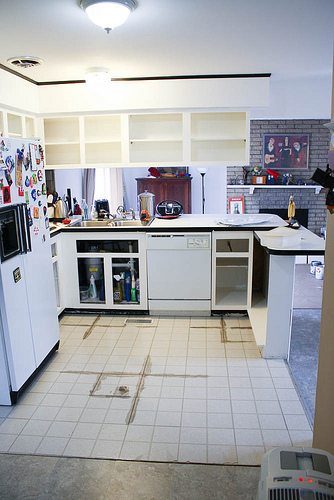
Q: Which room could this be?
A: It is a kitchen.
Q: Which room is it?
A: It is a kitchen.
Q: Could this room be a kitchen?
A: Yes, it is a kitchen.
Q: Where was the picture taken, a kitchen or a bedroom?
A: It was taken at a kitchen.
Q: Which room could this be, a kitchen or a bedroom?
A: It is a kitchen.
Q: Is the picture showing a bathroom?
A: No, the picture is showing a kitchen.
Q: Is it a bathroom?
A: No, it is a kitchen.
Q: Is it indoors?
A: Yes, it is indoors.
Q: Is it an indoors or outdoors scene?
A: It is indoors.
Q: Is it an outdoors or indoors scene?
A: It is indoors.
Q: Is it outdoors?
A: No, it is indoors.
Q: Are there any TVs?
A: No, there are no tvs.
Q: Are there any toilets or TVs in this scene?
A: No, there are no TVs or toilets.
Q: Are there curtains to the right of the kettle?
A: Yes, there is a curtain to the right of the kettle.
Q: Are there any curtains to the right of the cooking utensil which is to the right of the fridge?
A: Yes, there is a curtain to the right of the kettle.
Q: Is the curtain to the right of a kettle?
A: Yes, the curtain is to the right of a kettle.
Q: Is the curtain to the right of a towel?
A: No, the curtain is to the right of a kettle.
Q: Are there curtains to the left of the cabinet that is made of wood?
A: Yes, there is a curtain to the left of the cabinet.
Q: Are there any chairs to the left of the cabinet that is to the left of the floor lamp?
A: No, there is a curtain to the left of the cabinet.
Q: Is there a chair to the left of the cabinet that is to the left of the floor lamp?
A: No, there is a curtain to the left of the cabinet.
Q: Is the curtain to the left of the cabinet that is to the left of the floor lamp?
A: Yes, the curtain is to the left of the cabinet.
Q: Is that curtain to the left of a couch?
A: No, the curtain is to the left of the cabinet.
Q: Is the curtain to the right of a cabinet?
A: No, the curtain is to the left of a cabinet.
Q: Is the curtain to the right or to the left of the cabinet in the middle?
A: The curtain is to the left of the cabinet.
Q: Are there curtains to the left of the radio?
A: Yes, there is a curtain to the left of the radio.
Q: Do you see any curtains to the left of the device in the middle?
A: Yes, there is a curtain to the left of the radio.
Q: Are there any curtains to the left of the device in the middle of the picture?
A: Yes, there is a curtain to the left of the radio.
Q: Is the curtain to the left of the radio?
A: Yes, the curtain is to the left of the radio.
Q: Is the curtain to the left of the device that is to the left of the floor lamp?
A: Yes, the curtain is to the left of the radio.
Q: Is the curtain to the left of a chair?
A: No, the curtain is to the left of the radio.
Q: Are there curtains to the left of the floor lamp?
A: Yes, there is a curtain to the left of the floor lamp.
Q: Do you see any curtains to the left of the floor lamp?
A: Yes, there is a curtain to the left of the floor lamp.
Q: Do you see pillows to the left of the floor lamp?
A: No, there is a curtain to the left of the floor lamp.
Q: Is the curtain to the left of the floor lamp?
A: Yes, the curtain is to the left of the floor lamp.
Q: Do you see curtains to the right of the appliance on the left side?
A: Yes, there is a curtain to the right of the fridge.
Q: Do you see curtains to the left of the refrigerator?
A: No, the curtain is to the right of the refrigerator.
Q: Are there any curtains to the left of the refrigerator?
A: No, the curtain is to the right of the refrigerator.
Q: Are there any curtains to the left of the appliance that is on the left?
A: No, the curtain is to the right of the refrigerator.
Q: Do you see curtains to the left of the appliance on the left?
A: No, the curtain is to the right of the refrigerator.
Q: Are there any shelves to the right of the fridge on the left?
A: No, there is a curtain to the right of the freezer.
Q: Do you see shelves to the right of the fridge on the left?
A: No, there is a curtain to the right of the freezer.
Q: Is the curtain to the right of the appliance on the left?
A: Yes, the curtain is to the right of the refrigerator.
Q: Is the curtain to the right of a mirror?
A: No, the curtain is to the right of the refrigerator.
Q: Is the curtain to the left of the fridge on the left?
A: No, the curtain is to the right of the fridge.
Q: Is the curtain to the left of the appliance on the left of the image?
A: No, the curtain is to the right of the fridge.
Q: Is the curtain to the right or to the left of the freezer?
A: The curtain is to the right of the freezer.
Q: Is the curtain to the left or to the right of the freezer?
A: The curtain is to the right of the freezer.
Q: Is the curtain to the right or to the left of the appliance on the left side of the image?
A: The curtain is to the right of the freezer.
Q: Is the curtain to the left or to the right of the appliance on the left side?
A: The curtain is to the right of the freezer.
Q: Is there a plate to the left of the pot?
A: No, there is a curtain to the left of the pot.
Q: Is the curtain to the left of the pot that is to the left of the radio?
A: Yes, the curtain is to the left of the pot.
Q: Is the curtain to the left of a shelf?
A: No, the curtain is to the left of the pot.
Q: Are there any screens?
A: No, there are no screens.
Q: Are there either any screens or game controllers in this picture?
A: No, there are no screens or game controllers.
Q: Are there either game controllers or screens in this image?
A: No, there are no screens or game controllers.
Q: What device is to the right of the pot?
A: The device is a radio.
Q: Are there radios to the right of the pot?
A: Yes, there is a radio to the right of the pot.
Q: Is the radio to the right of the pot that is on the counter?
A: Yes, the radio is to the right of the pot.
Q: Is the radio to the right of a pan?
A: No, the radio is to the right of the pot.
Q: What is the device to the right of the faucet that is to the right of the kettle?
A: The device is a radio.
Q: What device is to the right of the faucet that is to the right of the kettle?
A: The device is a radio.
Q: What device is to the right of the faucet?
A: The device is a radio.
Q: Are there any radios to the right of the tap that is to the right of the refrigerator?
A: Yes, there is a radio to the right of the tap.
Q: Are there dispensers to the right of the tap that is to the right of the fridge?
A: No, there is a radio to the right of the faucet.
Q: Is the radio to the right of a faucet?
A: Yes, the radio is to the right of a faucet.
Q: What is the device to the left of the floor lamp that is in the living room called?
A: The device is a radio.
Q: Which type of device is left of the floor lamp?
A: The device is a radio.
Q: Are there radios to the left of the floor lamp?
A: Yes, there is a radio to the left of the floor lamp.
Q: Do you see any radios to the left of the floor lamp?
A: Yes, there is a radio to the left of the floor lamp.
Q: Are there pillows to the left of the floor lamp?
A: No, there is a radio to the left of the floor lamp.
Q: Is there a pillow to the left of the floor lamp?
A: No, there is a radio to the left of the floor lamp.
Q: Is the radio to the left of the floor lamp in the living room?
A: Yes, the radio is to the left of the floor lamp.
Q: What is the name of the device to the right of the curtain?
A: The device is a radio.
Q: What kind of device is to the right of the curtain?
A: The device is a radio.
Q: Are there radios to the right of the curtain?
A: Yes, there is a radio to the right of the curtain.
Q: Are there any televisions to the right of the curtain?
A: No, there is a radio to the right of the curtain.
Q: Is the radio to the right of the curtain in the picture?
A: Yes, the radio is to the right of the curtain.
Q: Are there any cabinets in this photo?
A: Yes, there is a cabinet.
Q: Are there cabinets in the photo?
A: Yes, there is a cabinet.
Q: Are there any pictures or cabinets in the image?
A: Yes, there is a cabinet.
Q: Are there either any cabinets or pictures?
A: Yes, there is a cabinet.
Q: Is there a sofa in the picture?
A: No, there are no sofas.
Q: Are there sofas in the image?
A: No, there are no sofas.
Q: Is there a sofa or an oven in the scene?
A: No, there are no sofas or ovens.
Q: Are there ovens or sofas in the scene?
A: No, there are no sofas or ovens.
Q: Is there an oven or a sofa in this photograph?
A: No, there are no sofas or ovens.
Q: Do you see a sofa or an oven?
A: No, there are no sofas or ovens.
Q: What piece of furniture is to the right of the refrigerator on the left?
A: The piece of furniture is a cabinet.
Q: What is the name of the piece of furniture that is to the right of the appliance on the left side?
A: The piece of furniture is a cabinet.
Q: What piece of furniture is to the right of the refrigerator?
A: The piece of furniture is a cabinet.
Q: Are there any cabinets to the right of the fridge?
A: Yes, there is a cabinet to the right of the fridge.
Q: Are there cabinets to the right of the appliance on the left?
A: Yes, there is a cabinet to the right of the fridge.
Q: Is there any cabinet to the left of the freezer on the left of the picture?
A: No, the cabinet is to the right of the freezer.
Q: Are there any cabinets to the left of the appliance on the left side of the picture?
A: No, the cabinet is to the right of the freezer.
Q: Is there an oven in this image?
A: No, there are no ovens.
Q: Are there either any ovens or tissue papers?
A: No, there are no ovens or tissue papers.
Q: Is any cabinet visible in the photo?
A: Yes, there is a cabinet.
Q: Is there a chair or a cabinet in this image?
A: Yes, there is a cabinet.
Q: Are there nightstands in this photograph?
A: No, there are no nightstands.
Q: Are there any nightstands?
A: No, there are no nightstands.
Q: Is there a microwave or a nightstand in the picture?
A: No, there are no nightstands or microwaves.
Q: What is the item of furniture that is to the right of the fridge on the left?
A: The piece of furniture is a cabinet.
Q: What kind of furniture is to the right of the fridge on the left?
A: The piece of furniture is a cabinet.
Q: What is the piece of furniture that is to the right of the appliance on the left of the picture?
A: The piece of furniture is a cabinet.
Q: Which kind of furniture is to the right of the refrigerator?
A: The piece of furniture is a cabinet.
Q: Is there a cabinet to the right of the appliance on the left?
A: Yes, there is a cabinet to the right of the freezer.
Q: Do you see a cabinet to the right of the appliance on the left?
A: Yes, there is a cabinet to the right of the freezer.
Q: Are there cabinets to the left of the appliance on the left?
A: No, the cabinet is to the right of the fridge.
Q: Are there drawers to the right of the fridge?
A: No, there is a cabinet to the right of the fridge.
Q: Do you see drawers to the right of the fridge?
A: No, there is a cabinet to the right of the fridge.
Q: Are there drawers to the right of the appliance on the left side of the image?
A: No, there is a cabinet to the right of the fridge.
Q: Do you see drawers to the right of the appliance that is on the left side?
A: No, there is a cabinet to the right of the fridge.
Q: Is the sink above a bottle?
A: Yes, the sink is above a bottle.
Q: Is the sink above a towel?
A: No, the sink is above a bottle.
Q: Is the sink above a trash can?
A: No, the sink is above a bottle.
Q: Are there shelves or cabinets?
A: Yes, there is a cabinet.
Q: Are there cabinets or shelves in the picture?
A: Yes, there is a cabinet.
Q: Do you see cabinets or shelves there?
A: Yes, there is a cabinet.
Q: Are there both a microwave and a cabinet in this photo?
A: No, there is a cabinet but no microwaves.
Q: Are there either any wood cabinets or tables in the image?
A: Yes, there is a wood cabinet.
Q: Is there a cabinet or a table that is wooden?
A: Yes, the cabinet is wooden.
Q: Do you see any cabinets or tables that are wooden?
A: Yes, the cabinet is wooden.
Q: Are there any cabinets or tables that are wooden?
A: Yes, the cabinet is wooden.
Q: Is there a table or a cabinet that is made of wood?
A: Yes, the cabinet is made of wood.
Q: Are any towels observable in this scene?
A: No, there are no towels.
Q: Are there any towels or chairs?
A: No, there are no towels or chairs.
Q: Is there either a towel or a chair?
A: No, there are no towels or chairs.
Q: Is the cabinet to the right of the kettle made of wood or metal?
A: The cabinet is made of wood.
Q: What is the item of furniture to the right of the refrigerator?
A: The piece of furniture is a cabinet.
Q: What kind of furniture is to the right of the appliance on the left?
A: The piece of furniture is a cabinet.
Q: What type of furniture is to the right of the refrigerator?
A: The piece of furniture is a cabinet.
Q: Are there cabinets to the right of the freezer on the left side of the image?
A: Yes, there is a cabinet to the right of the fridge.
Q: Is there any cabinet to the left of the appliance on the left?
A: No, the cabinet is to the right of the refrigerator.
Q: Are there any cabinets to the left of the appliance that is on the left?
A: No, the cabinet is to the right of the refrigerator.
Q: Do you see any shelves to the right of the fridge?
A: No, there is a cabinet to the right of the fridge.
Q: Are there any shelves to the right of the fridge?
A: No, there is a cabinet to the right of the fridge.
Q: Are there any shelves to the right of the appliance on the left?
A: No, there is a cabinet to the right of the fridge.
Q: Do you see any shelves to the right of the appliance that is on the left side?
A: No, there is a cabinet to the right of the fridge.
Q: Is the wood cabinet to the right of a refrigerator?
A: Yes, the cabinet is to the right of a refrigerator.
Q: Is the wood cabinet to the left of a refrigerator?
A: No, the cabinet is to the right of a refrigerator.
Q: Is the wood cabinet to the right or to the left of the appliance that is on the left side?
A: The cabinet is to the right of the freezer.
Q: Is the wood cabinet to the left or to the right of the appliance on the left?
A: The cabinet is to the right of the freezer.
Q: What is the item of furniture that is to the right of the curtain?
A: The piece of furniture is a cabinet.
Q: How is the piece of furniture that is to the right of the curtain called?
A: The piece of furniture is a cabinet.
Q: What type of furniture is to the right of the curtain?
A: The piece of furniture is a cabinet.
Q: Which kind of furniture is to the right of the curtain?
A: The piece of furniture is a cabinet.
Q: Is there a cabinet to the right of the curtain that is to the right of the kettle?
A: Yes, there is a cabinet to the right of the curtain.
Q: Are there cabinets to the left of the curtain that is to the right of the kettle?
A: No, the cabinet is to the right of the curtain.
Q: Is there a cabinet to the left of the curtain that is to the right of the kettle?
A: No, the cabinet is to the right of the curtain.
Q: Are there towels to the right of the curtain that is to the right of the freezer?
A: No, there is a cabinet to the right of the curtain.